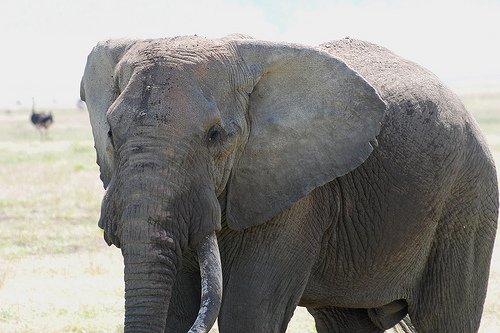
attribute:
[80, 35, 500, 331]
elephant — big, old, wrinkled, gray, adult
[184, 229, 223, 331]
tusk — large, brow, gray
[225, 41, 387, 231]
ear — large, big, gray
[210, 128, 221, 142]
eye — small, dark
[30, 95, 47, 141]
ostrich — tall, black, brown, white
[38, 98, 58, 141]
ostrich — tall, brown, black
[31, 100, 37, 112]
neck — long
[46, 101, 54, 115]
neck — long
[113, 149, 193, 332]
trunk — long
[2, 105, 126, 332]
field — grassy, green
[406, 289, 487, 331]
leg — hid leg